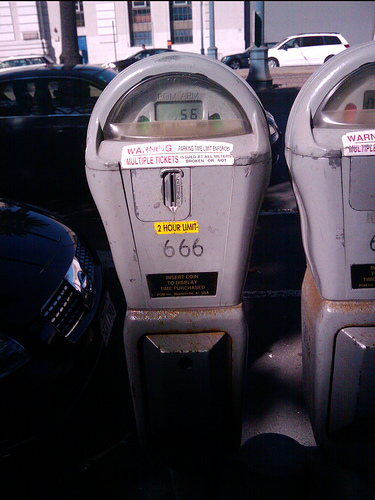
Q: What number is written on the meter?
A: 666.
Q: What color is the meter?
A: Gray.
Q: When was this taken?
A: Daytime.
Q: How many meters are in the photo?
A: 2.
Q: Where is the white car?
A: Street.